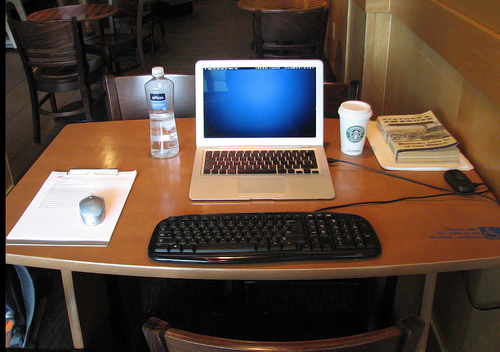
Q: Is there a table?
A: Yes, there is a table.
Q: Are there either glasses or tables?
A: Yes, there is a table.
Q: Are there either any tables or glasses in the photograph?
A: Yes, there is a table.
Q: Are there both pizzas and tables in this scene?
A: No, there is a table but no pizzas.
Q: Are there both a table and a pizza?
A: No, there is a table but no pizzas.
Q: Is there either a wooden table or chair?
A: Yes, there is a wood table.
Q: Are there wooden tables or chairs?
A: Yes, there is a wood table.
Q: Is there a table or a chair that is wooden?
A: Yes, the table is wooden.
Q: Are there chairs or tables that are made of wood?
A: Yes, the table is made of wood.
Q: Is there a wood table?
A: Yes, there is a table that is made of wood.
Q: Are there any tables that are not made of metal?
A: Yes, there is a table that is made of wood.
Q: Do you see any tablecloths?
A: No, there are no tablecloths.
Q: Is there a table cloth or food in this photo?
A: No, there are no tablecloths or food.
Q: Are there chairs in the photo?
A: Yes, there is a chair.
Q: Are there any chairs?
A: Yes, there is a chair.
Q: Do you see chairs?
A: Yes, there is a chair.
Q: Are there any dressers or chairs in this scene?
A: Yes, there is a chair.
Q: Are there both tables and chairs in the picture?
A: Yes, there are both a chair and a table.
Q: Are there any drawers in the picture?
A: No, there are no drawers.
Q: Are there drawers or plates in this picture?
A: No, there are no drawers or plates.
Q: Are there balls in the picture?
A: No, there are no balls.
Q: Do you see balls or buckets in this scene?
A: No, there are no balls or buckets.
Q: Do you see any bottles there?
A: Yes, there is a bottle.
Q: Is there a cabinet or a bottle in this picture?
A: Yes, there is a bottle.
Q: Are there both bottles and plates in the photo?
A: No, there is a bottle but no plates.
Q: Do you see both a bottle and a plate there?
A: No, there is a bottle but no plates.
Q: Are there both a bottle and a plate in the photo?
A: No, there is a bottle but no plates.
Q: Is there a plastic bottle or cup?
A: Yes, there is a plastic bottle.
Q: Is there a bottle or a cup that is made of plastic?
A: Yes, the bottle is made of plastic.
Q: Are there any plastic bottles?
A: Yes, there is a bottle that is made of plastic.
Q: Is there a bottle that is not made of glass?
A: Yes, there is a bottle that is made of plastic.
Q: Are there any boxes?
A: No, there are no boxes.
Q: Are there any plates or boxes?
A: No, there are no boxes or plates.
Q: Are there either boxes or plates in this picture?
A: No, there are no boxes or plates.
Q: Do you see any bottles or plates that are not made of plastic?
A: No, there is a bottle but it is made of plastic.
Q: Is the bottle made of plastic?
A: Yes, the bottle is made of plastic.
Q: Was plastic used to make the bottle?
A: Yes, the bottle is made of plastic.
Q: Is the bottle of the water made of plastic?
A: Yes, the bottle is made of plastic.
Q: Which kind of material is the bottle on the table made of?
A: The bottle is made of plastic.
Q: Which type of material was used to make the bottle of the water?
A: The bottle is made of plastic.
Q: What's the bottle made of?
A: The bottle is made of plastic.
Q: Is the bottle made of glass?
A: No, the bottle is made of plastic.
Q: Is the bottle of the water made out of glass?
A: No, the bottle is made of plastic.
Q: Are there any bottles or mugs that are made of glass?
A: No, there is a bottle but it is made of plastic.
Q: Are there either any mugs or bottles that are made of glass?
A: No, there is a bottle but it is made of plastic.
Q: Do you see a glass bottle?
A: No, there is a bottle but it is made of plastic.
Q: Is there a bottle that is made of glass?
A: No, there is a bottle but it is made of plastic.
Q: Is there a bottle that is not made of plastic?
A: No, there is a bottle but it is made of plastic.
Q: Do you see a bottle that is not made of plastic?
A: No, there is a bottle but it is made of plastic.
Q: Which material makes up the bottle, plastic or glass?
A: The bottle is made of plastic.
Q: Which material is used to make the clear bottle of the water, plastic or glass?
A: The bottle is made of plastic.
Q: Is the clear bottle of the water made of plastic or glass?
A: The bottle is made of plastic.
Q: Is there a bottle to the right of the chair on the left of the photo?
A: Yes, there is a bottle to the right of the chair.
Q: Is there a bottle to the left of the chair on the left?
A: No, the bottle is to the right of the chair.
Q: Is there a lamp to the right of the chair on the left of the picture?
A: No, there is a bottle to the right of the chair.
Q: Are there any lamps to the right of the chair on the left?
A: No, there is a bottle to the right of the chair.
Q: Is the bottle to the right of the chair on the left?
A: Yes, the bottle is to the right of the chair.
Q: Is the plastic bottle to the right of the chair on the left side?
A: Yes, the bottle is to the right of the chair.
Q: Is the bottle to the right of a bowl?
A: No, the bottle is to the right of the chair.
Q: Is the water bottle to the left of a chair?
A: No, the bottle is to the right of a chair.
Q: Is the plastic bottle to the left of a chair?
A: No, the bottle is to the right of a chair.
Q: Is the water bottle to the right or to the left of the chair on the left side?
A: The bottle is to the right of the chair.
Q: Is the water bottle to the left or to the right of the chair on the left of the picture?
A: The bottle is to the right of the chair.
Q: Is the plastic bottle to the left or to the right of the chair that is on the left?
A: The bottle is to the right of the chair.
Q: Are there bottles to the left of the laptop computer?
A: Yes, there is a bottle to the left of the laptop computer.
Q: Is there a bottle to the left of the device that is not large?
A: Yes, there is a bottle to the left of the laptop computer.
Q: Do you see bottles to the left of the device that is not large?
A: Yes, there is a bottle to the left of the laptop computer.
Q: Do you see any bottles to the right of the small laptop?
A: No, the bottle is to the left of the laptop computer.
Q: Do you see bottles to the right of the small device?
A: No, the bottle is to the left of the laptop computer.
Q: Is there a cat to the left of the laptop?
A: No, there is a bottle to the left of the laptop.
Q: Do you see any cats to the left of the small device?
A: No, there is a bottle to the left of the laptop.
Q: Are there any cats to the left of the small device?
A: No, there is a bottle to the left of the laptop.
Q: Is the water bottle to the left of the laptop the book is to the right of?
A: Yes, the bottle is to the left of the laptop computer.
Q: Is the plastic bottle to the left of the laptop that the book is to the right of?
A: Yes, the bottle is to the left of the laptop computer.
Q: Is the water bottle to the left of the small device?
A: Yes, the bottle is to the left of the laptop computer.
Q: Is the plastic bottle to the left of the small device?
A: Yes, the bottle is to the left of the laptop computer.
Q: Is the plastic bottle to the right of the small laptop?
A: No, the bottle is to the left of the laptop.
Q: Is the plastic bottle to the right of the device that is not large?
A: No, the bottle is to the left of the laptop.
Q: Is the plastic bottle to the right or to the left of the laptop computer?
A: The bottle is to the left of the laptop computer.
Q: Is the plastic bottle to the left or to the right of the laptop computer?
A: The bottle is to the left of the laptop computer.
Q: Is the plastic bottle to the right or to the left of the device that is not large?
A: The bottle is to the left of the laptop computer.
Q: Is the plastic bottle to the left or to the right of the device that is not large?
A: The bottle is to the left of the laptop computer.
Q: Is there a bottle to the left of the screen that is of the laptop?
A: Yes, there is a bottle to the left of the screen.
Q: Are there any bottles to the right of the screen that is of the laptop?
A: No, the bottle is to the left of the screen.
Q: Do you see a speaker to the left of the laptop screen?
A: No, there is a bottle to the left of the screen.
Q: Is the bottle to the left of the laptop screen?
A: Yes, the bottle is to the left of the screen.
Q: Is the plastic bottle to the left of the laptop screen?
A: Yes, the bottle is to the left of the screen.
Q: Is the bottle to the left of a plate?
A: No, the bottle is to the left of the screen.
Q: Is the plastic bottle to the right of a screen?
A: No, the bottle is to the left of a screen.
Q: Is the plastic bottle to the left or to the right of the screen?
A: The bottle is to the left of the screen.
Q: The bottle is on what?
A: The bottle is on the table.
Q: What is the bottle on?
A: The bottle is on the table.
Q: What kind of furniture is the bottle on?
A: The bottle is on the table.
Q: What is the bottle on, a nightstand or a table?
A: The bottle is on a table.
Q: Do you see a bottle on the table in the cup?
A: Yes, there is a bottle on the table.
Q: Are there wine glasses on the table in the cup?
A: No, there is a bottle on the table.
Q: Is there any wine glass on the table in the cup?
A: No, there is a bottle on the table.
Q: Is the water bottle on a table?
A: Yes, the bottle is on a table.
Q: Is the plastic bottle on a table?
A: Yes, the bottle is on a table.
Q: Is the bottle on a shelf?
A: No, the bottle is on a table.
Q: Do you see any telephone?
A: No, there are no phones.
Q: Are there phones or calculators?
A: No, there are no phones or calculators.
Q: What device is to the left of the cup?
A: The device is a screen.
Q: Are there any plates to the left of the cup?
A: No, there is a screen to the left of the cup.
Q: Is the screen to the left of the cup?
A: Yes, the screen is to the left of the cup.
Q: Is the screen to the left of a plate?
A: No, the screen is to the left of the cup.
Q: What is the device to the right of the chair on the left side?
A: The device is a screen.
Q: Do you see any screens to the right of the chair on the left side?
A: Yes, there is a screen to the right of the chair.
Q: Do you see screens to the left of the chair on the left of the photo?
A: No, the screen is to the right of the chair.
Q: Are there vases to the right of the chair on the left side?
A: No, there is a screen to the right of the chair.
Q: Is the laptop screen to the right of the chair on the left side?
A: Yes, the screen is to the right of the chair.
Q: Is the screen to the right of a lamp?
A: No, the screen is to the right of the chair.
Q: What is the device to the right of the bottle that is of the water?
A: The device is a screen.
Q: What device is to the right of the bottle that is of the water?
A: The device is a screen.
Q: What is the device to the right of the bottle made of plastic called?
A: The device is a screen.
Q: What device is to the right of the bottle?
A: The device is a screen.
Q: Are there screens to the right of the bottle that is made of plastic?
A: Yes, there is a screen to the right of the bottle.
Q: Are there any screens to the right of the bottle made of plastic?
A: Yes, there is a screen to the right of the bottle.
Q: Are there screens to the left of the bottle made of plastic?
A: No, the screen is to the right of the bottle.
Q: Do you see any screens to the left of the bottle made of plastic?
A: No, the screen is to the right of the bottle.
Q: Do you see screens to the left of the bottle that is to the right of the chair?
A: No, the screen is to the right of the bottle.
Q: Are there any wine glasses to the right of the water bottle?
A: No, there is a screen to the right of the bottle.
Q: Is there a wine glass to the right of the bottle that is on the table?
A: No, there is a screen to the right of the bottle.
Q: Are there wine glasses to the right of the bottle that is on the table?
A: No, there is a screen to the right of the bottle.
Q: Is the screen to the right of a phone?
A: No, the screen is to the right of the bottle.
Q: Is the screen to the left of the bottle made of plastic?
A: No, the screen is to the right of the bottle.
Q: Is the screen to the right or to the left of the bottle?
A: The screen is to the right of the bottle.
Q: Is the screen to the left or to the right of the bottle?
A: The screen is to the right of the bottle.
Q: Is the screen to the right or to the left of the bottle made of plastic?
A: The screen is to the right of the bottle.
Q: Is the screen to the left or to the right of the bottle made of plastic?
A: The screen is to the right of the bottle.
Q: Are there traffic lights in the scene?
A: No, there are no traffic lights.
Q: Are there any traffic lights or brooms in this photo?
A: No, there are no traffic lights or brooms.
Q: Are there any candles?
A: No, there are no candles.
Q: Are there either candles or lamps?
A: No, there are no candles or lamps.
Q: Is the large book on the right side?
A: Yes, the book is on the right of the image.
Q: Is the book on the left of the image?
A: No, the book is on the right of the image.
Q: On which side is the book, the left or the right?
A: The book is on the right of the image.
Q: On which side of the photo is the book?
A: The book is on the right of the image.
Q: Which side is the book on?
A: The book is on the right of the image.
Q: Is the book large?
A: Yes, the book is large.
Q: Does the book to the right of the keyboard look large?
A: Yes, the book is large.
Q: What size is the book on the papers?
A: The book is large.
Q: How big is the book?
A: The book is large.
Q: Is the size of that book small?
A: No, the book is large.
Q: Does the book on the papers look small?
A: No, the book is large.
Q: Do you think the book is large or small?
A: The book is large.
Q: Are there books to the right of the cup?
A: Yes, there is a book to the right of the cup.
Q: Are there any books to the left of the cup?
A: No, the book is to the right of the cup.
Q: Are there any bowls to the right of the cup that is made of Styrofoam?
A: No, there is a book to the right of the cup.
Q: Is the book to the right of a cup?
A: Yes, the book is to the right of a cup.